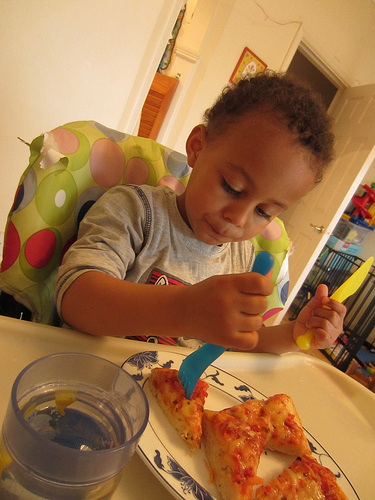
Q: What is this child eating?
A: Pizza.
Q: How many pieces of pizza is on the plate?
A: Four.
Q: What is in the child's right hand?
A: A fork.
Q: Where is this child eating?
A: The kitchen.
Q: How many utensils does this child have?
A: Two.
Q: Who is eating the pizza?
A: A child.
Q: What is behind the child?
A: A door.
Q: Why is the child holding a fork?
A: To eat the pizza with.